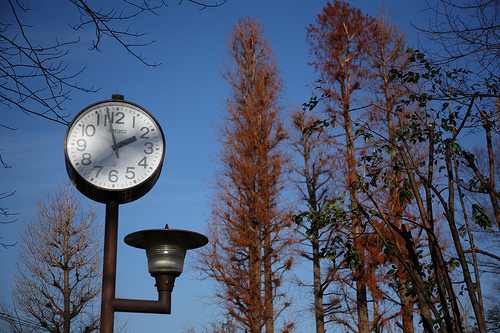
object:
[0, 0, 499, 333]
sky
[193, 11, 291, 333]
trees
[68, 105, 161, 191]
face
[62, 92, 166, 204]
clock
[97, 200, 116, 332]
post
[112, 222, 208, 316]
light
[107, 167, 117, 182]
numbers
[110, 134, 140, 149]
hands